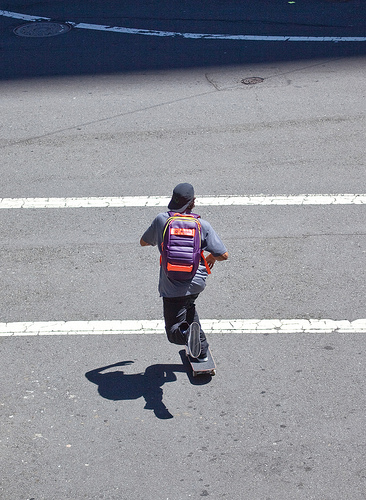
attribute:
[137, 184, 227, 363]
man — dark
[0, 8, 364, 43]
lines — white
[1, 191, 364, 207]
lines — white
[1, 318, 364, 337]
lines — white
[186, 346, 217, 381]
skateboard — black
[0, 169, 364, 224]
line — white, cracked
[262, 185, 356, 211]
paint — white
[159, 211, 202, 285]
bookbag — in picture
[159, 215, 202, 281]
backpack — purple and orange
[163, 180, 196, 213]
hat — black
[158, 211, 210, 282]
backpack — red and purple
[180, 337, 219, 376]
skateboard — in picture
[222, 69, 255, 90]
gutter — small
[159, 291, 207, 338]
pants — black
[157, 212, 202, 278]
bag — purple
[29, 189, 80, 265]
line — white